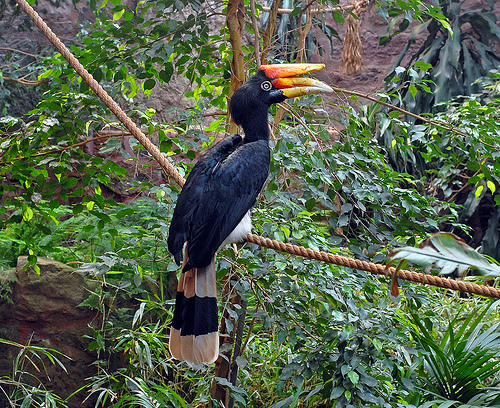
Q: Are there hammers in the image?
A: No, there are no hammers.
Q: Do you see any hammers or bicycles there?
A: No, there are no hammers or bicycles.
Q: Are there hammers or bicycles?
A: No, there are no hammers or bicycles.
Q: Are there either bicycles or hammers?
A: No, there are no hammers or bicycles.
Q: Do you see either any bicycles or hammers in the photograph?
A: No, there are no hammers or bicycles.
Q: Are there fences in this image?
A: No, there are no fences.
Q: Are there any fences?
A: No, there are no fences.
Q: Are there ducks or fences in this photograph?
A: No, there are no fences or ducks.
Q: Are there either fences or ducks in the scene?
A: No, there are no fences or ducks.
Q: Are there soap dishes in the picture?
A: No, there are no soap dishes.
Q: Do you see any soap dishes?
A: No, there are no soap dishes.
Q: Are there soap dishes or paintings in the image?
A: No, there are no soap dishes or paintings.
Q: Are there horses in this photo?
A: No, there are no horses.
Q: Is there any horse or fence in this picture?
A: No, there are no horses or fences.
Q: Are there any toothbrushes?
A: No, there are no toothbrushes.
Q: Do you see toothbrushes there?
A: No, there are no toothbrushes.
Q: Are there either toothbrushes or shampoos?
A: No, there are no toothbrushes or shampoos.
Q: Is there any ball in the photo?
A: No, there are no balls.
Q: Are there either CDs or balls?
A: No, there are no balls or cds.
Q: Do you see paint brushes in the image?
A: No, there are no paint brushes.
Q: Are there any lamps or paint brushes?
A: No, there are no paint brushes or lamps.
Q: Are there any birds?
A: Yes, there is a bird.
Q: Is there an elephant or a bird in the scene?
A: Yes, there is a bird.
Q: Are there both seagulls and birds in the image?
A: No, there is a bird but no seagulls.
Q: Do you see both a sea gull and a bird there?
A: No, there is a bird but no seagulls.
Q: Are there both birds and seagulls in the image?
A: No, there is a bird but no seagulls.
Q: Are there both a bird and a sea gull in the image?
A: No, there is a bird but no seagulls.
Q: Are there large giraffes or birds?
A: Yes, there is a large bird.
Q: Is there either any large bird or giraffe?
A: Yes, there is a large bird.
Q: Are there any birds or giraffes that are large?
A: Yes, the bird is large.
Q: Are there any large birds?
A: Yes, there is a large bird.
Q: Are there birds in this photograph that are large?
A: Yes, there is a bird that is large.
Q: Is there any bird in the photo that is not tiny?
A: Yes, there is a large bird.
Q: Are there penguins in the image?
A: No, there are no penguins.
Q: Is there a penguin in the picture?
A: No, there are no penguins.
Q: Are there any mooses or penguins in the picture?
A: No, there are no penguins or mooses.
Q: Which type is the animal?
A: The animal is a bird.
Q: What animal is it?
A: The animal is a bird.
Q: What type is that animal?
A: This is a bird.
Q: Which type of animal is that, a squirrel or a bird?
A: This is a bird.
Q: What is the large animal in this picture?
A: The animal is a bird.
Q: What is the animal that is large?
A: The animal is a bird.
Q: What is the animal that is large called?
A: The animal is a bird.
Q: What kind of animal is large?
A: The animal is a bird.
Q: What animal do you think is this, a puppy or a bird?
A: This is a bird.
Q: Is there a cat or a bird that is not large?
A: No, there is a bird but it is large.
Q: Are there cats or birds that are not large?
A: No, there is a bird but it is large.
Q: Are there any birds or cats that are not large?
A: No, there is a bird but it is large.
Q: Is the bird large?
A: Yes, the bird is large.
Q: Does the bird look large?
A: Yes, the bird is large.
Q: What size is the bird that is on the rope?
A: The bird is large.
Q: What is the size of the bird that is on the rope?
A: The bird is large.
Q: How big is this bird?
A: The bird is large.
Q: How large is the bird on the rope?
A: The bird is large.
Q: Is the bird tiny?
A: No, the bird is large.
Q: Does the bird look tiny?
A: No, the bird is large.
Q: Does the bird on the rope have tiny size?
A: No, the bird is large.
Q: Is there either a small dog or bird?
A: No, there is a bird but it is large.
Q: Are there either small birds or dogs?
A: No, there is a bird but it is large.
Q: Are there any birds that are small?
A: No, there is a bird but it is large.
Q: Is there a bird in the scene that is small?
A: No, there is a bird but it is large.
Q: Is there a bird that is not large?
A: No, there is a bird but it is large.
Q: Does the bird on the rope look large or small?
A: The bird is large.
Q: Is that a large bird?
A: Yes, that is a large bird.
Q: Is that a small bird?
A: No, that is a large bird.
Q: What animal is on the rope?
A: The bird is on the rope.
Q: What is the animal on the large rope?
A: The animal is a bird.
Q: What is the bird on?
A: The bird is on the rope.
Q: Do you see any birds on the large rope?
A: Yes, there is a bird on the rope.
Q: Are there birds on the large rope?
A: Yes, there is a bird on the rope.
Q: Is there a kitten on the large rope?
A: No, there is a bird on the rope.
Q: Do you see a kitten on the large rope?
A: No, there is a bird on the rope.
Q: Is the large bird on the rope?
A: Yes, the bird is on the rope.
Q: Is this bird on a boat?
A: No, the bird is on the rope.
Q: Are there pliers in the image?
A: No, there are no pliers.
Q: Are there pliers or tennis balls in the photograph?
A: No, there are no pliers or tennis balls.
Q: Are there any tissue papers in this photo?
A: No, there are no tissue papers.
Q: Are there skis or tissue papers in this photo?
A: No, there are no tissue papers or skis.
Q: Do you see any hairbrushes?
A: No, there are no hairbrushes.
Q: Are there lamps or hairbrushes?
A: No, there are no hairbrushes or lamps.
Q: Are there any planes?
A: No, there are no planes.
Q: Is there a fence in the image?
A: No, there are no fences.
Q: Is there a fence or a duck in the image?
A: No, there are no fences or ducks.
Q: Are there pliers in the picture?
A: No, there are no pliers.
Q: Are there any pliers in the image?
A: No, there are no pliers.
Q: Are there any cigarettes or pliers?
A: No, there are no pliers or cigarettes.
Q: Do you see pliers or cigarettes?
A: No, there are no pliers or cigarettes.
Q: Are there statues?
A: No, there are no statues.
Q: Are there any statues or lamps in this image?
A: No, there are no statues or lamps.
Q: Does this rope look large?
A: Yes, the rope is large.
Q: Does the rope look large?
A: Yes, the rope is large.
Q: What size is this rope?
A: The rope is large.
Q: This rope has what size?
A: The rope is large.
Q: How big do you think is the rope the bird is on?
A: The rope is large.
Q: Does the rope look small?
A: No, the rope is large.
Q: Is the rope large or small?
A: The rope is large.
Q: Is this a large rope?
A: Yes, this is a large rope.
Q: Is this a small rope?
A: No, this is a large rope.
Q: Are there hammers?
A: No, there are no hammers.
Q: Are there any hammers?
A: No, there are no hammers.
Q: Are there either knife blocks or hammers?
A: No, there are no hammers or knife blocks.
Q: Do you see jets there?
A: No, there are no jets.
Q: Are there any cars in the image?
A: No, there are no cars.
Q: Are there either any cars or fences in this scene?
A: No, there are no cars or fences.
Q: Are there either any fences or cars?
A: No, there are no cars or fences.